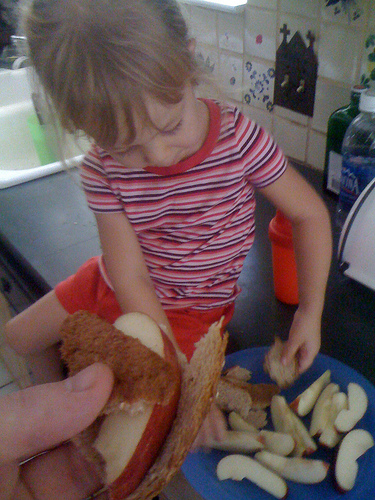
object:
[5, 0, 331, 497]
toddler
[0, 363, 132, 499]
hand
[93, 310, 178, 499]
apple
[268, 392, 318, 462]
apple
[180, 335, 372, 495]
dish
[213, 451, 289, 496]
slice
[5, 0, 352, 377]
girl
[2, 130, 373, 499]
counter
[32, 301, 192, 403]
food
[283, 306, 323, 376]
hand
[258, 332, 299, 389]
bread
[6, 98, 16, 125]
white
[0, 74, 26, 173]
sink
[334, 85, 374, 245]
bottle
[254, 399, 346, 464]
apple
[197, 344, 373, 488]
plate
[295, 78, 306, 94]
light switch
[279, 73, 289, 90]
light switch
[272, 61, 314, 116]
swich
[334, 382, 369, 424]
apple slice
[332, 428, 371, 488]
apple slice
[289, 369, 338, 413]
apple slice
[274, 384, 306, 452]
apple slice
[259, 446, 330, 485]
apple slice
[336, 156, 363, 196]
label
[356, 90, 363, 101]
lid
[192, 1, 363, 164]
wall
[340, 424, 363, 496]
slice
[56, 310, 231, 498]
bread